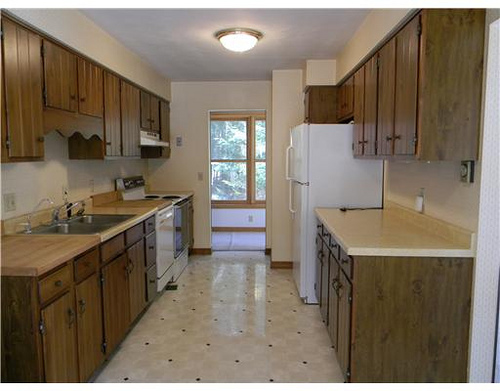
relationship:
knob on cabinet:
[71, 94, 77, 104] [40, 34, 80, 117]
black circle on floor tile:
[169, 358, 174, 362] [90, 249, 341, 380]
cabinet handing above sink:
[40, 34, 80, 117] [19, 221, 123, 236]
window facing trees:
[211, 120, 249, 203] [211, 118, 246, 198]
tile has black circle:
[90, 249, 341, 380] [234, 359, 240, 364]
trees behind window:
[211, 118, 246, 198] [211, 120, 249, 203]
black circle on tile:
[144, 341, 150, 347] [90, 249, 341, 380]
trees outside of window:
[211, 118, 246, 198] [211, 120, 249, 203]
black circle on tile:
[169, 358, 174, 362] [90, 249, 341, 380]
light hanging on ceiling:
[214, 29, 264, 54] [82, 9, 375, 83]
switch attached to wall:
[458, 160, 475, 185] [382, 157, 481, 234]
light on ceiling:
[214, 29, 264, 54] [82, 9, 375, 83]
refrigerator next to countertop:
[285, 122, 384, 302] [315, 196, 475, 257]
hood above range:
[142, 126, 172, 145] [116, 171, 191, 284]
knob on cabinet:
[75, 92, 86, 104] [74, 55, 108, 124]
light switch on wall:
[3, 190, 16, 214] [2, 126, 146, 219]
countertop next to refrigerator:
[315, 196, 475, 257] [285, 122, 384, 302]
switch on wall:
[458, 160, 475, 185] [382, 157, 481, 234]